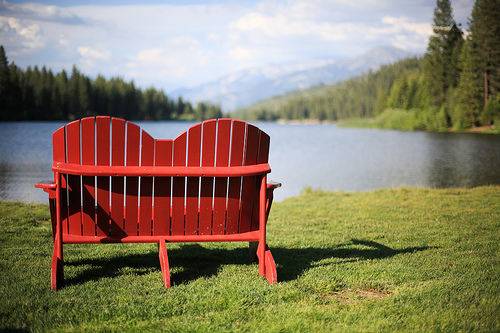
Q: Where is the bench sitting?
A: On grass.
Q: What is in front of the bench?
A: Water.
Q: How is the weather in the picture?
A: Cloudy.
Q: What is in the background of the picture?
A: Mountains.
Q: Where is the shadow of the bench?
A: On the ground.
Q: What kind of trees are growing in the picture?
A: Pine trees.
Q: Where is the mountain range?
A: Beyond the pine trees.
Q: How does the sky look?
A: Cloudy and overcast.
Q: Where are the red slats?
A: On back of bench.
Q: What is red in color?
A: The two person bench.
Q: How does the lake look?
A: Still, smooth, and calm.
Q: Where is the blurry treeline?
A: Behind a lake.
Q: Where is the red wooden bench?
A: At the water's edge.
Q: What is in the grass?
A: The shadow of a bench.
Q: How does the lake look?
A: Beautiful and placid.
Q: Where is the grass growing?
A: At the side of a lake.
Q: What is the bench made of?
A: Wood.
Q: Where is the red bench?
A: On the grass.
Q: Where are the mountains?
A: In the distance.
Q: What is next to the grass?
A: A body of water.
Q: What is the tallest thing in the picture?
A: Tree.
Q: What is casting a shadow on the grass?
A: The red bench.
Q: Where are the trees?
A: On the other side of the shoreline.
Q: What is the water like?
A: Still.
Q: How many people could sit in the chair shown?
A: Two.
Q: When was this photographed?
A: Day time.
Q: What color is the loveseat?
A: Red.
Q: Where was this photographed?
A: A lake.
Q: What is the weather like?
A: Partly cloudy.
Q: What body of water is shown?
A: A lake.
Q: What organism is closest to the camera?
A: Grass.